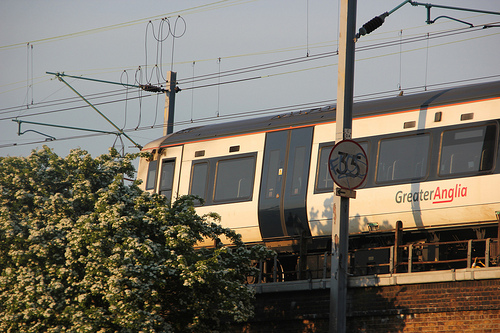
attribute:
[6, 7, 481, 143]
wires — electrical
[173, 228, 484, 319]
bridge — worn, brick, old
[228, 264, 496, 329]
wall — bricked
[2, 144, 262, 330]
plant — large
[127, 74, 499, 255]
train — traveling, white, black, elevated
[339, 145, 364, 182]
number — 35, blue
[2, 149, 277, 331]
bush — large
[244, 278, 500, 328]
wall — brick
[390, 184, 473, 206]
sign — round, white, red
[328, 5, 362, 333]
pole — metal, black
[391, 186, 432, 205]
word — green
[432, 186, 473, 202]
word — red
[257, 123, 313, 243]
door — glass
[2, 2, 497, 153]
sky — clear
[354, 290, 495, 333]
brick — brown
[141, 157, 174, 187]
window — side